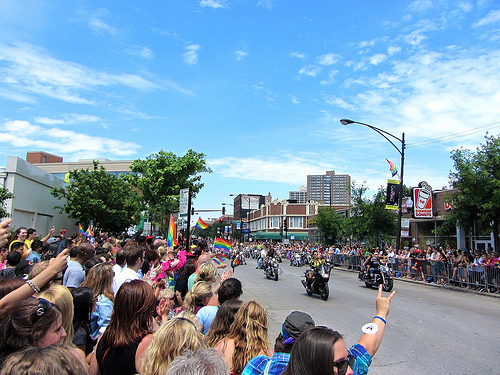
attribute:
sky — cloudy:
[2, 2, 494, 227]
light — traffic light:
[219, 205, 227, 217]